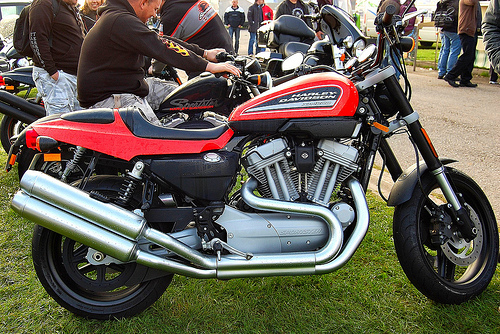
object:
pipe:
[7, 168, 380, 280]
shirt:
[72, 0, 209, 110]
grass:
[1, 80, 498, 333]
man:
[2, 0, 91, 113]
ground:
[418, 122, 468, 154]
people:
[432, 0, 457, 78]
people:
[372, 0, 414, 35]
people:
[481, 0, 498, 80]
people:
[223, 1, 245, 52]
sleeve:
[146, 34, 202, 74]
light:
[418, 127, 439, 158]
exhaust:
[10, 165, 216, 279]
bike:
[2, 5, 499, 319]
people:
[441, 0, 480, 87]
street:
[398, 72, 490, 151]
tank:
[226, 71, 363, 131]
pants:
[32, 66, 77, 115]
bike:
[0, 7, 325, 177]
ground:
[3, 45, 498, 332]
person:
[248, 0, 273, 56]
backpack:
[12, 7, 31, 69]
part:
[347, 244, 398, 296]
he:
[73, 0, 236, 124]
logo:
[158, 36, 187, 56]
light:
[35, 134, 59, 153]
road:
[368, 61, 462, 215]